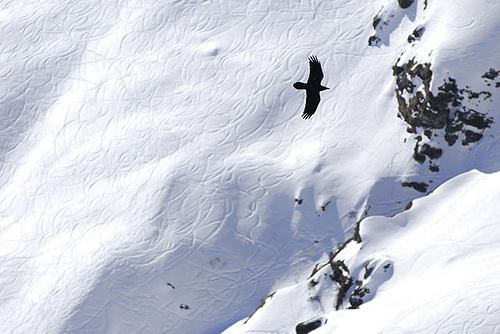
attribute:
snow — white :
[198, 232, 262, 283]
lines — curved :
[203, 101, 269, 155]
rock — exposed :
[316, 259, 373, 305]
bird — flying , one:
[294, 54, 331, 119]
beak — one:
[315, 80, 328, 96]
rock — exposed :
[398, 177, 438, 198]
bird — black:
[288, 46, 332, 120]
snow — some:
[20, 24, 257, 207]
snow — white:
[80, 40, 189, 176]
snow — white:
[230, 174, 372, 288]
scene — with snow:
[1, 3, 441, 327]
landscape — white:
[4, 3, 496, 332]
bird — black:
[293, 53, 330, 116]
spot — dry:
[413, 86, 466, 136]